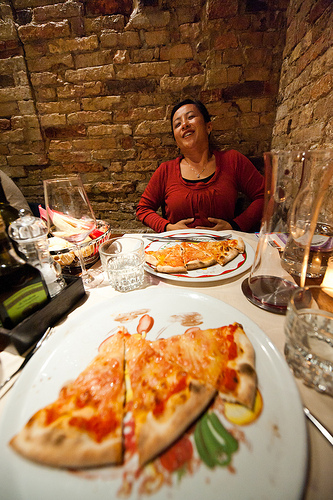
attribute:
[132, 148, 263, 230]
shirt — red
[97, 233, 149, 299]
crystal glass — small, clear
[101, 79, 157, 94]
brick — wall 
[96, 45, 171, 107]
wall —  brick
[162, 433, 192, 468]
pepperoni — red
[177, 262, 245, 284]
plate — red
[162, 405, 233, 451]
leaf — green 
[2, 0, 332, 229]
brick wall — wall 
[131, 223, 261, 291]
plate — slices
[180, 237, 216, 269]
pizza — five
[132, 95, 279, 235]
woman — seated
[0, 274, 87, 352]
basket — black 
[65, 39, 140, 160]
bricks — behind the lady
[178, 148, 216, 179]
neck — woman's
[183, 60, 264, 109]
brick — distressed